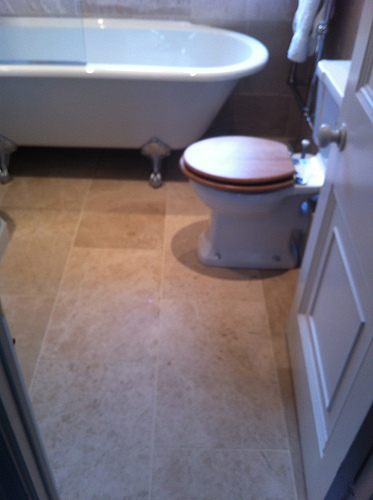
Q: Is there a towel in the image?
A: Yes, there is a towel.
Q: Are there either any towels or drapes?
A: Yes, there is a towel.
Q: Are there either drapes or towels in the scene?
A: Yes, there is a towel.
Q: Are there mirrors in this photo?
A: No, there are no mirrors.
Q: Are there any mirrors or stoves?
A: No, there are no mirrors or stoves.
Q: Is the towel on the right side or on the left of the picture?
A: The towel is on the right of the image.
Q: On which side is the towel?
A: The towel is on the right of the image.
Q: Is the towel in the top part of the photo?
A: Yes, the towel is in the top of the image.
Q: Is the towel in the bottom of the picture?
A: No, the towel is in the top of the image.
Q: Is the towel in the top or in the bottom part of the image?
A: The towel is in the top of the image.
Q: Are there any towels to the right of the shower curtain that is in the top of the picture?
A: Yes, there is a towel to the right of the shower curtain.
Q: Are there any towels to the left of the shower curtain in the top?
A: No, the towel is to the right of the shower curtain.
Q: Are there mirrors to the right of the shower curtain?
A: No, there is a towel to the right of the shower curtain.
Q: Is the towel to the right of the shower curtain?
A: Yes, the towel is to the right of the shower curtain.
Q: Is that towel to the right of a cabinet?
A: No, the towel is to the right of the shower curtain.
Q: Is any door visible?
A: Yes, there is a door.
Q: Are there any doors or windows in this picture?
A: Yes, there is a door.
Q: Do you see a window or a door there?
A: Yes, there is a door.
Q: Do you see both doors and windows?
A: No, there is a door but no windows.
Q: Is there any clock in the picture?
A: No, there are no clocks.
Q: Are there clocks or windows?
A: No, there are no clocks or windows.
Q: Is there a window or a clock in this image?
A: No, there are no clocks or windows.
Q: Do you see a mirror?
A: No, there are no mirrors.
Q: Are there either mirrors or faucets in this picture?
A: No, there are no mirrors or faucets.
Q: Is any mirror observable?
A: No, there are no mirrors.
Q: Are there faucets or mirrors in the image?
A: No, there are no mirrors or faucets.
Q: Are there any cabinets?
A: No, there are no cabinets.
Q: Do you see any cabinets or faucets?
A: No, there are no cabinets or faucets.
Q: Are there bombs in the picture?
A: No, there are no bombs.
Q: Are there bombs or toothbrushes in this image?
A: No, there are no bombs or toothbrushes.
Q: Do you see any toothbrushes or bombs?
A: No, there are no bombs or toothbrushes.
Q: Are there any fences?
A: No, there are no fences.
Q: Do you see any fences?
A: No, there are no fences.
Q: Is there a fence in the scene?
A: No, there are no fences.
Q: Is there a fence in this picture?
A: No, there are no fences.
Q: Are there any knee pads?
A: No, there are no knee pads.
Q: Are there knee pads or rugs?
A: No, there are no knee pads or rugs.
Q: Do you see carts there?
A: No, there are no carts.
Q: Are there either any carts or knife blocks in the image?
A: No, there are no carts or knife blocks.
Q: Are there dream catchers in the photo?
A: No, there are no dream catchers.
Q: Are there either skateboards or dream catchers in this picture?
A: No, there are no dream catchers or skateboards.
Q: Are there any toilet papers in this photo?
A: No, there are no toilet papers.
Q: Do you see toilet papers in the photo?
A: No, there are no toilet papers.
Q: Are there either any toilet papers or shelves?
A: No, there are no toilet papers or shelves.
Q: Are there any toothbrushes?
A: No, there are no toothbrushes.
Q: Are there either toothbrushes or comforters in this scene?
A: No, there are no toothbrushes or comforters.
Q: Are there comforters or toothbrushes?
A: No, there are no toothbrushes or comforters.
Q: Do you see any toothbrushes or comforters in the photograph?
A: No, there are no toothbrushes or comforters.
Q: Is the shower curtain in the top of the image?
A: Yes, the shower curtain is in the top of the image.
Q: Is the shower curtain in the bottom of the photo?
A: No, the shower curtain is in the top of the image.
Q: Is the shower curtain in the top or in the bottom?
A: The shower curtain is in the top of the image.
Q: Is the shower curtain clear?
A: Yes, the shower curtain is clear.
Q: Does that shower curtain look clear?
A: Yes, the shower curtain is clear.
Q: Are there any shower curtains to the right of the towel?
A: No, the shower curtain is to the left of the towel.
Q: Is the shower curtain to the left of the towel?
A: Yes, the shower curtain is to the left of the towel.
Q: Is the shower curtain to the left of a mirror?
A: No, the shower curtain is to the left of the towel.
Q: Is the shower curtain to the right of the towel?
A: No, the shower curtain is to the left of the towel.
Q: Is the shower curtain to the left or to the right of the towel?
A: The shower curtain is to the left of the towel.